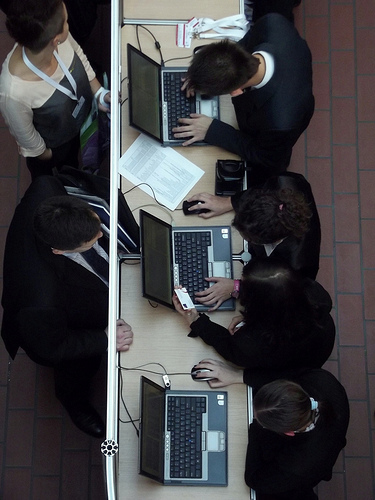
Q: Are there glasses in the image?
A: No, there are no glasses.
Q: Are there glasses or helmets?
A: No, there are no glasses or helmets.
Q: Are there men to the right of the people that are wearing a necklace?
A: Yes, there is a man to the right of the people.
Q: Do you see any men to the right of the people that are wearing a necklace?
A: Yes, there is a man to the right of the people.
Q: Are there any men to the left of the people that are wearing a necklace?
A: No, the man is to the right of the people.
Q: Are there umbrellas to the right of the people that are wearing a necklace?
A: No, there is a man to the right of the people.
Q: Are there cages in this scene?
A: No, there are no cages.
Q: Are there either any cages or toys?
A: No, there are no cages or toys.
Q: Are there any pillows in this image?
A: No, there are no pillows.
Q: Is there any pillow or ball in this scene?
A: No, there are no pillows or balls.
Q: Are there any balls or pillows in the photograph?
A: No, there are no pillows or balls.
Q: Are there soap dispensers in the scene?
A: No, there are no soap dispensers.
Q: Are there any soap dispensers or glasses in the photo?
A: No, there are no soap dispensers or glasses.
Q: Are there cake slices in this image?
A: No, there are no cake slices.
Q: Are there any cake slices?
A: No, there are no cake slices.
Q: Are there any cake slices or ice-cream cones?
A: No, there are no cake slices or ice-cream cones.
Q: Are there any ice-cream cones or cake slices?
A: No, there are no cake slices or ice-cream cones.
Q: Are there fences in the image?
A: No, there are no fences.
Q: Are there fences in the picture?
A: No, there are no fences.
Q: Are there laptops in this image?
A: Yes, there is a laptop.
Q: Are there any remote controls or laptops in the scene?
A: Yes, there is a laptop.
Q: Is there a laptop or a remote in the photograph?
A: Yes, there is a laptop.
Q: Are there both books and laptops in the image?
A: No, there is a laptop but no books.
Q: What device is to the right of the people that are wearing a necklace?
A: The device is a laptop.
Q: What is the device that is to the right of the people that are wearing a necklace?
A: The device is a laptop.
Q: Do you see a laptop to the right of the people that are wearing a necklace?
A: Yes, there is a laptop to the right of the people.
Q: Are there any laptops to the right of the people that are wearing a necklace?
A: Yes, there is a laptop to the right of the people.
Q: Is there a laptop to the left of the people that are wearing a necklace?
A: No, the laptop is to the right of the people.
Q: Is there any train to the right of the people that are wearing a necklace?
A: No, there is a laptop to the right of the people.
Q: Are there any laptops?
A: Yes, there is a laptop.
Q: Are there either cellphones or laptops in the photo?
A: Yes, there is a laptop.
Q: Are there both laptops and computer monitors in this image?
A: No, there is a laptop but no computer monitors.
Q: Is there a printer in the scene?
A: No, there are no printers.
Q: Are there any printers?
A: No, there are no printers.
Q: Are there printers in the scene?
A: No, there are no printers.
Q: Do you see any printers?
A: No, there are no printers.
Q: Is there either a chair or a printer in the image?
A: No, there are no printers or chairs.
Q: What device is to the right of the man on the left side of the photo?
A: The device is a laptop.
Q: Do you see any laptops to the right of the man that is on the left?
A: Yes, there is a laptop to the right of the man.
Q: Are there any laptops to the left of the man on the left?
A: No, the laptop is to the right of the man.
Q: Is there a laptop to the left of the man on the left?
A: No, the laptop is to the right of the man.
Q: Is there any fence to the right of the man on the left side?
A: No, there is a laptop to the right of the man.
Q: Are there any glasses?
A: No, there are no glasses.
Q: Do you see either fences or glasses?
A: No, there are no glasses or fences.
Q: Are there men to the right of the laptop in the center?
A: No, the man is to the left of the laptop computer.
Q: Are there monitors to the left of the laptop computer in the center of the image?
A: No, there is a man to the left of the laptop.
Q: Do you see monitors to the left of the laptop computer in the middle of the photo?
A: No, there is a man to the left of the laptop.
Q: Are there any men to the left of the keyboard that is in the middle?
A: Yes, there is a man to the left of the keyboard.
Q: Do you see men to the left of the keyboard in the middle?
A: Yes, there is a man to the left of the keyboard.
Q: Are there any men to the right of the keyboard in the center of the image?
A: No, the man is to the left of the keyboard.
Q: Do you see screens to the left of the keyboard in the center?
A: No, there is a man to the left of the keyboard.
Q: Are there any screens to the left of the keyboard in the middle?
A: No, there is a man to the left of the keyboard.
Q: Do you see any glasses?
A: No, there are no glasses.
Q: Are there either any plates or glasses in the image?
A: No, there are no glasses or plates.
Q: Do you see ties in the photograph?
A: Yes, there is a tie.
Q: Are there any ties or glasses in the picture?
A: Yes, there is a tie.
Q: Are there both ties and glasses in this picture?
A: No, there is a tie but no glasses.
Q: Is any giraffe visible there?
A: No, there are no giraffes.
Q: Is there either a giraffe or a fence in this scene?
A: No, there are no giraffes or fences.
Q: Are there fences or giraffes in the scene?
A: No, there are no giraffes or fences.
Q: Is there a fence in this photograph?
A: No, there are no fences.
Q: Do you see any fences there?
A: No, there are no fences.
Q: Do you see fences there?
A: No, there are no fences.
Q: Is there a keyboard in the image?
A: Yes, there is a keyboard.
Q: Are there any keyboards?
A: Yes, there is a keyboard.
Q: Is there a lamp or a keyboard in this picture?
A: Yes, there is a keyboard.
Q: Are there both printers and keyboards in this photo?
A: No, there is a keyboard but no printers.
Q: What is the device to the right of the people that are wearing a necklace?
A: The device is a keyboard.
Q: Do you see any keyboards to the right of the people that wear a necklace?
A: Yes, there is a keyboard to the right of the people.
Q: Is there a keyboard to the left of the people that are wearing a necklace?
A: No, the keyboard is to the right of the people.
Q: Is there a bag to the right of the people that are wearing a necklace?
A: No, there is a keyboard to the right of the people.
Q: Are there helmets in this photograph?
A: No, there are no helmets.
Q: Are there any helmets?
A: No, there are no helmets.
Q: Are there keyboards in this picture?
A: Yes, there is a keyboard.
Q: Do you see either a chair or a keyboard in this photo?
A: Yes, there is a keyboard.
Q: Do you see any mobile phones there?
A: No, there are no mobile phones.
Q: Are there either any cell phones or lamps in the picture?
A: No, there are no cell phones or lamps.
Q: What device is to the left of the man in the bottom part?
A: The device is a keyboard.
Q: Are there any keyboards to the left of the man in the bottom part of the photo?
A: Yes, there is a keyboard to the left of the man.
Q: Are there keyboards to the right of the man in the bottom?
A: No, the keyboard is to the left of the man.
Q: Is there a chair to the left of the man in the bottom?
A: No, there is a keyboard to the left of the man.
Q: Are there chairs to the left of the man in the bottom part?
A: No, there is a keyboard to the left of the man.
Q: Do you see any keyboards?
A: Yes, there is a keyboard.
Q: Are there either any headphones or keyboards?
A: Yes, there is a keyboard.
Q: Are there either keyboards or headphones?
A: Yes, there is a keyboard.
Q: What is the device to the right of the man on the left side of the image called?
A: The device is a keyboard.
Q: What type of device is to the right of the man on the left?
A: The device is a keyboard.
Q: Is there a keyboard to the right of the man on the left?
A: Yes, there is a keyboard to the right of the man.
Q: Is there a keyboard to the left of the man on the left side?
A: No, the keyboard is to the right of the man.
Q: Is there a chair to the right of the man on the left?
A: No, there is a keyboard to the right of the man.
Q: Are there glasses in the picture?
A: No, there are no glasses.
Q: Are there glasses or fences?
A: No, there are no glasses or fences.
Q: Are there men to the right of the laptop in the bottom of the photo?
A: Yes, there is a man to the right of the laptop.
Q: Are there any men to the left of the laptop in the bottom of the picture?
A: No, the man is to the right of the laptop.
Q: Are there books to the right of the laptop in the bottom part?
A: No, there is a man to the right of the laptop.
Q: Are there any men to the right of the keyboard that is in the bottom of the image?
A: Yes, there is a man to the right of the keyboard.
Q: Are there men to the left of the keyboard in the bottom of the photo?
A: No, the man is to the right of the keyboard.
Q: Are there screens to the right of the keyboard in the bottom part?
A: No, there is a man to the right of the keyboard.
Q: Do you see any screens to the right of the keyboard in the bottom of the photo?
A: No, there is a man to the right of the keyboard.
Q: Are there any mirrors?
A: No, there are no mirrors.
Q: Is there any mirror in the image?
A: No, there are no mirrors.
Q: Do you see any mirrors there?
A: No, there are no mirrors.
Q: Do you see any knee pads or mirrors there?
A: No, there are no mirrors or knee pads.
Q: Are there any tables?
A: Yes, there is a table.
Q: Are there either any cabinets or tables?
A: Yes, there is a table.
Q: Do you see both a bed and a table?
A: No, there is a table but no beds.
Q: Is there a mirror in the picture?
A: No, there are no mirrors.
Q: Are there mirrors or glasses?
A: No, there are no mirrors or glasses.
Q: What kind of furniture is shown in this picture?
A: The furniture is a table.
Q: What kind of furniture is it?
A: The piece of furniture is a table.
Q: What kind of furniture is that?
A: This is a table.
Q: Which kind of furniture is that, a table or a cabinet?
A: This is a table.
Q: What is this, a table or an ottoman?
A: This is a table.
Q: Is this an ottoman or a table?
A: This is a table.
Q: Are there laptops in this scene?
A: Yes, there is a laptop.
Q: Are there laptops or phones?
A: Yes, there is a laptop.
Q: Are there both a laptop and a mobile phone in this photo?
A: No, there is a laptop but no cell phones.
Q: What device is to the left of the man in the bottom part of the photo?
A: The device is a laptop.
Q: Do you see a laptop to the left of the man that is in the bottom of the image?
A: Yes, there is a laptop to the left of the man.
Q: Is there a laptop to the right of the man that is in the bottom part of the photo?
A: No, the laptop is to the left of the man.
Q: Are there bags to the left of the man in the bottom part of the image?
A: No, there is a laptop to the left of the man.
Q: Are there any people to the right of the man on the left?
A: Yes, there is a person to the right of the man.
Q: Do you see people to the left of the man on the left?
A: No, the person is to the right of the man.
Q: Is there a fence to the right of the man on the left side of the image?
A: No, there is a person to the right of the man.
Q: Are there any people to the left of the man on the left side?
A: No, the person is to the right of the man.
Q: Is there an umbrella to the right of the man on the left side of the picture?
A: No, there is a person to the right of the man.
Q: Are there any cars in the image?
A: No, there are no cars.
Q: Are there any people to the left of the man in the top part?
A: Yes, there are people to the left of the man.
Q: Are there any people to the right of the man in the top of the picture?
A: No, the people are to the left of the man.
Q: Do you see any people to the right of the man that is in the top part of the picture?
A: No, the people are to the left of the man.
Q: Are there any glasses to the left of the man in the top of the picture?
A: No, there are people to the left of the man.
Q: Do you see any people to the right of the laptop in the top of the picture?
A: No, the people are to the left of the laptop.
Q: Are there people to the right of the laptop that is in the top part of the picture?
A: No, the people are to the left of the laptop.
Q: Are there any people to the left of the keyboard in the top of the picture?
A: Yes, there are people to the left of the keyboard.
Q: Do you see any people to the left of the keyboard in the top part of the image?
A: Yes, there are people to the left of the keyboard.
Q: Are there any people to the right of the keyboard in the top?
A: No, the people are to the left of the keyboard.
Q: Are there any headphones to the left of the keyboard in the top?
A: No, there are people to the left of the keyboard.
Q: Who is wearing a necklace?
A: The people are wearing a necklace.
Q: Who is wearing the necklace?
A: The people are wearing a necklace.